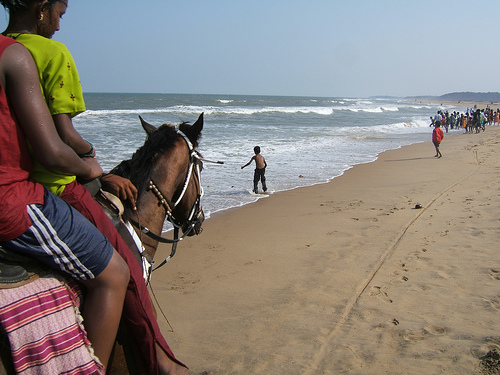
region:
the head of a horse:
[133, 108, 215, 240]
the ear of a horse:
[187, 107, 209, 137]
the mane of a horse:
[111, 114, 182, 209]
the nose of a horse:
[194, 208, 208, 230]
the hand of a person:
[101, 169, 146, 214]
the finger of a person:
[123, 185, 140, 212]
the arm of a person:
[1, 37, 88, 178]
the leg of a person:
[11, 180, 134, 374]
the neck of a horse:
[108, 152, 172, 267]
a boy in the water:
[234, 142, 276, 203]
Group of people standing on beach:
[411, 103, 498, 157]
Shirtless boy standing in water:
[234, 136, 284, 202]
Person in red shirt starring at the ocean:
[421, 118, 453, 159]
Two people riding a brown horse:
[8, 7, 232, 373]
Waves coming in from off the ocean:
[104, 95, 492, 175]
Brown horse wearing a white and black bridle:
[116, 108, 248, 373]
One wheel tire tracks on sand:
[321, 185, 466, 374]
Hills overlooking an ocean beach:
[425, 77, 497, 107]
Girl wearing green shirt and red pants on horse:
[7, 2, 209, 372]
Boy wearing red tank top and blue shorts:
[6, 11, 159, 368]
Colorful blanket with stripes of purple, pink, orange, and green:
[2, 292, 106, 374]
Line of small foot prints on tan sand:
[369, 207, 448, 338]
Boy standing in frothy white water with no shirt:
[234, 137, 276, 207]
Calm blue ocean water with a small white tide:
[104, 86, 349, 116]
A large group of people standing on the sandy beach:
[430, 102, 493, 149]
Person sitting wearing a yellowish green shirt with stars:
[8, 0, 85, 143]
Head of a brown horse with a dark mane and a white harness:
[132, 117, 221, 239]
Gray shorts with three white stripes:
[9, 201, 111, 277]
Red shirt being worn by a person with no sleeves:
[0, 35, 55, 230]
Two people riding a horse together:
[0, 6, 212, 336]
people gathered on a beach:
[429, 103, 498, 135]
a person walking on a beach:
[429, 120, 444, 158]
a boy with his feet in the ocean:
[239, 145, 269, 193]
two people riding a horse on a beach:
[1, 1, 206, 373]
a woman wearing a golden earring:
[33, 8, 45, 25]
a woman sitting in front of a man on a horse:
[1, 0, 140, 374]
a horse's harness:
[115, 127, 205, 274]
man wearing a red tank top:
[0, 33, 47, 245]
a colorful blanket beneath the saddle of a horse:
[0, 268, 103, 373]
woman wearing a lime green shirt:
[6, 30, 85, 193]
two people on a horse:
[3, 30, 103, 177]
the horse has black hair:
[125, 150, 149, 175]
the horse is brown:
[160, 149, 213, 228]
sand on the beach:
[250, 210, 441, 348]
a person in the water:
[242, 148, 284, 193]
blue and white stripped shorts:
[21, 216, 115, 273]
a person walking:
[425, 119, 452, 162]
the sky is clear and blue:
[295, 12, 404, 67]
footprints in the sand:
[383, 263, 423, 296]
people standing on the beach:
[442, 108, 487, 127]